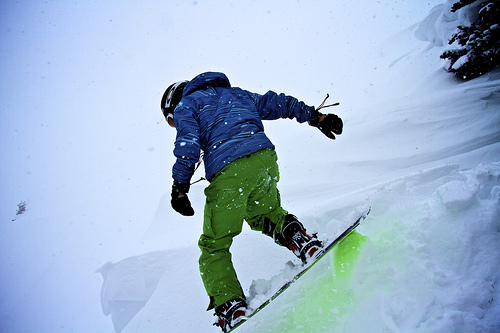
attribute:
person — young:
[160, 65, 316, 245]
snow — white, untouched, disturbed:
[1, 63, 463, 325]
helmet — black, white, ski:
[157, 81, 194, 133]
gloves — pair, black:
[175, 109, 353, 216]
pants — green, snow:
[206, 172, 277, 264]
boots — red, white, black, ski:
[230, 224, 313, 323]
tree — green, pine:
[438, 6, 495, 72]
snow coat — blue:
[183, 85, 271, 155]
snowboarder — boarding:
[161, 78, 341, 289]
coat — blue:
[190, 81, 271, 151]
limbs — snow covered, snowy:
[441, 47, 472, 60]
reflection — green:
[253, 244, 378, 323]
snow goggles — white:
[165, 107, 178, 125]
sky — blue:
[4, 11, 144, 107]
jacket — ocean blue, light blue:
[177, 80, 272, 154]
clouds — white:
[15, 17, 159, 115]